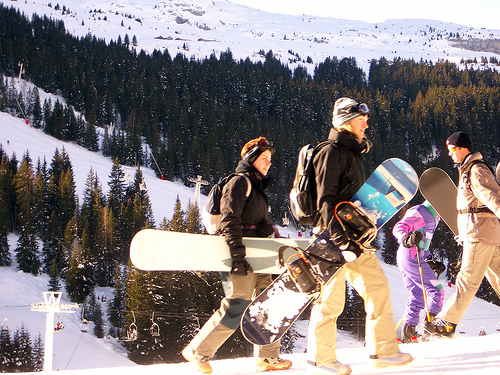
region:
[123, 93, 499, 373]
snowboarders on their way to play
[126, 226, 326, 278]
this young lady's snowboard is white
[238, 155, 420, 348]
this snowboarder's board is multi-colored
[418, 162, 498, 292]
this snowboarder's board is brown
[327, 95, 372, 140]
this snowboarder is wearing a ski cap and goggles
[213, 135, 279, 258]
this snowboarder is wearing a dark ski jacket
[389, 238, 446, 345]
this skier is wearing purple ski pants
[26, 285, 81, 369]
a support of the ski lift below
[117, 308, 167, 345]
skiers riding the ski lift up the mountain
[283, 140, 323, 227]
this snowboarder is wearing a backpack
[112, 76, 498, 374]
people walking on the snow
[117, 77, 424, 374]
two people carrying snowboards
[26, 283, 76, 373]
ski lift on the slope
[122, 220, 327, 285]
white and gray snowboard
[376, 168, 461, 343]
person on skis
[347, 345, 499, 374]
shadow on the gorund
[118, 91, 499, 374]
a group of four people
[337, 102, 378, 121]
goggles around the top of the head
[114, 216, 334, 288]
snowboard under the arm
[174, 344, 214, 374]
heel is lifted off the ground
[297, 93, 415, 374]
Man wearing a black jacket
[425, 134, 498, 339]
Man wearing brown pants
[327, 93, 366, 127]
Hat on man's head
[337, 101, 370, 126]
Goggles on man's hat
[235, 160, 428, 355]
Snowboard under man's arm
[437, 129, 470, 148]
Hat on man's head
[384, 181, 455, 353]
Girl wearing a purple snowsuit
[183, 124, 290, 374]
Woman wearing a black jacker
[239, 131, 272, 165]
Headband on the woman's head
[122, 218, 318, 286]
Snowboard under the woman's arm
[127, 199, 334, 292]
A white snowboard.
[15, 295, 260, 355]
A ski lift.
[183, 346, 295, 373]
A pair of snowboarding boots.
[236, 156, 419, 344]
A person carrying a blue snowboard.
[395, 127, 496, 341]
A purple snow suit.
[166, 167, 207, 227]
A ski lift in the background.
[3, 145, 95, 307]
A group of trees on the ski slope.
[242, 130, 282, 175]
A pair of red ski goggles.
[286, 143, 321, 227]
A backpack on a snowboarder.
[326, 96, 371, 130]
A gray winter hat.